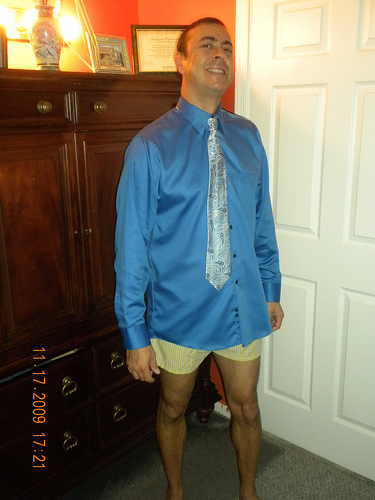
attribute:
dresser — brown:
[0, 68, 231, 499]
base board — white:
[217, 401, 228, 417]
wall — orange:
[140, 3, 232, 26]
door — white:
[334, 272, 369, 373]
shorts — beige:
[148, 334, 263, 374]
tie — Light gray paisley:
[184, 112, 242, 291]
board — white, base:
[11, 40, 98, 71]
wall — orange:
[2, 0, 137, 68]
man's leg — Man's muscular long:
[156, 367, 196, 497]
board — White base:
[214, 397, 235, 421]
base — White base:
[215, 402, 234, 422]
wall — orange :
[210, 364, 223, 387]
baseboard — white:
[210, 402, 235, 419]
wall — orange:
[208, 362, 229, 407]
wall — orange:
[99, 2, 225, 15]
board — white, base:
[212, 398, 236, 420]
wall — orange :
[81, 1, 234, 71]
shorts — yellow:
[148, 334, 271, 372]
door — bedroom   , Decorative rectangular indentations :
[234, 1, 372, 486]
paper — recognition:
[127, 23, 209, 73]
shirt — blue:
[101, 96, 291, 361]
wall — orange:
[1, 1, 236, 408]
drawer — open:
[149, 330, 328, 387]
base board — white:
[213, 402, 233, 421]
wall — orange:
[83, 0, 234, 77]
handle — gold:
[59, 371, 79, 397]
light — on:
[53, 13, 84, 48]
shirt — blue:
[120, 103, 274, 322]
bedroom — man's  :
[1, 6, 236, 115]